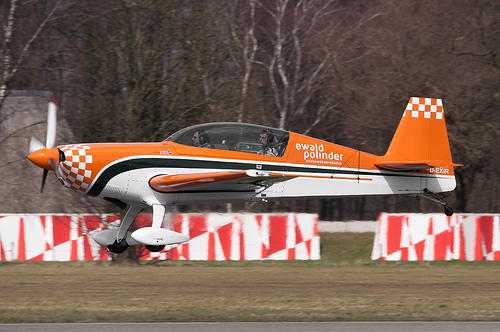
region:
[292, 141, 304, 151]
white letter on plane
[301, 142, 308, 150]
white letter on plane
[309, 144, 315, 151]
white letter on plane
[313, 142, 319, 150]
white letter on plane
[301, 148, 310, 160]
white letter on plane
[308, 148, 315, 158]
white letter on plane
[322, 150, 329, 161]
white letter on plane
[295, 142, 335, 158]
the letters are white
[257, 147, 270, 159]
the shirt is striped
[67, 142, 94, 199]
the pattern is plaid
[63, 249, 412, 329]
the grass is dry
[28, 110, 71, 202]
the propeller is moving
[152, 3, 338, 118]
the trees are bare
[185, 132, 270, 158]
two men in the plane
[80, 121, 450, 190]
the plane is orange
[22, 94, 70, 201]
propeller in front of plane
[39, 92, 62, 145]
blade of propeller is gray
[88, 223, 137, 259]
left wheel of plane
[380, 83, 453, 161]
vertical stabilizer of plane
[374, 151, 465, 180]
horizontal stabilizer of plane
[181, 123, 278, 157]
two people in the plane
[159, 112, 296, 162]
cockpit of the plane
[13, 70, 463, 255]
plane is white and orange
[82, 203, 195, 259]
structure holding the wheels are white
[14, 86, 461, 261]
Small orange and white aircraft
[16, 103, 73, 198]
large propeller on front of aircraft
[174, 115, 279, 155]
two men inside the plane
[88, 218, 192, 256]
planes landing gear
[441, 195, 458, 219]
rear planes landing gear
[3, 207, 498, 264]
red and white checkered banner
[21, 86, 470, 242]
two men flying plane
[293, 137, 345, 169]
plane has a name imprinted on it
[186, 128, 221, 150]
Pilot is wearing a headset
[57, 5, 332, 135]
large brown bare trees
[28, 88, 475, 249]
2 Man in orange airplane.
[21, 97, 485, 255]
Orange airplane with orange nose.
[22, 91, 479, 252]
Orange airplane with propellers.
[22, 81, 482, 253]
Orange airplane with tail.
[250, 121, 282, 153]
Man in back seat wearing head phones.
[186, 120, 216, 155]
Man in front seat wearing headphones.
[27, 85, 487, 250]
Orange airplane with front wheel on right side.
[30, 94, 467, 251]
Orange airplane with front wheel on left side.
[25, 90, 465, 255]
Orange airplane with letters written on side.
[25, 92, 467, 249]
Orange airplane with letters written on tail.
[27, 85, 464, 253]
the orange and white airplane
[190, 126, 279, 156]
the men in the airplane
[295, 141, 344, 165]
the white letters on the airplane